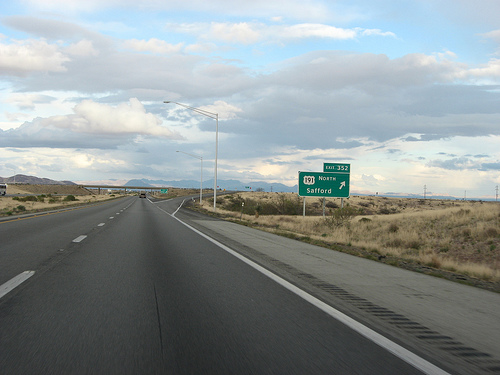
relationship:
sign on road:
[297, 159, 356, 203] [4, 192, 448, 372]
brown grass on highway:
[184, 190, 498, 280] [54, 183, 496, 370]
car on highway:
[136, 190, 150, 201] [1, 192, 498, 373]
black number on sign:
[305, 177, 308, 182] [303, 163, 349, 197]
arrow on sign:
[339, 181, 345, 190] [291, 159, 353, 209]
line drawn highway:
[168, 195, 454, 373] [1, 192, 498, 373]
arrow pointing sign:
[335, 179, 347, 190] [287, 167, 352, 211]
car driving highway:
[138, 190, 146, 199] [54, 209, 194, 319]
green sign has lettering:
[298, 171, 350, 197] [303, 174, 339, 194]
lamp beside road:
[162, 94, 225, 211] [2, 191, 498, 363]